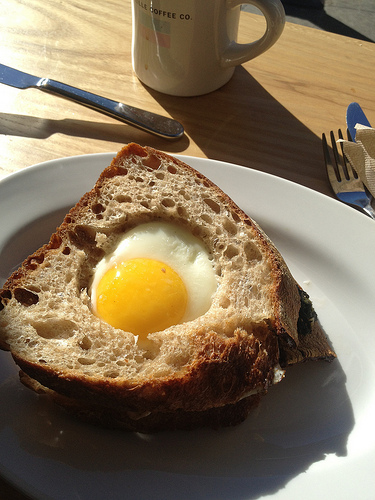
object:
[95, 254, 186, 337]
yolk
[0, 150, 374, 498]
plate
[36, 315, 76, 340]
hole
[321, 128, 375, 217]
fork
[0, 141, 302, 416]
bread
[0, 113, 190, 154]
shadow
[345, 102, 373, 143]
knife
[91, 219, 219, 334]
egg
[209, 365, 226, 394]
brown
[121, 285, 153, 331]
yellow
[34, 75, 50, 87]
shiny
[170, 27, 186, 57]
white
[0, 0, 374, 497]
table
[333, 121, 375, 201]
napkin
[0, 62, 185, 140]
knife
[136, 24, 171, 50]
print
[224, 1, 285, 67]
handle